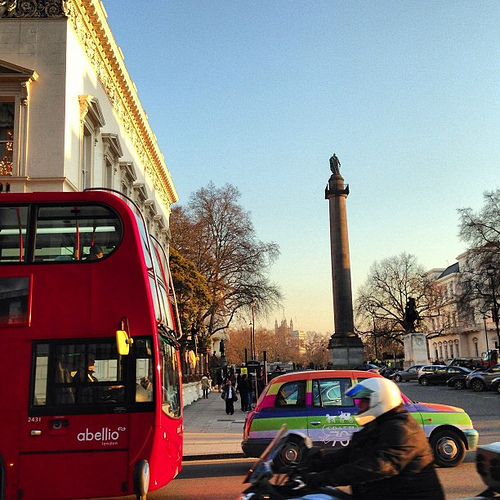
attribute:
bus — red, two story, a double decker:
[0, 187, 182, 498]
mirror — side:
[116, 328, 131, 354]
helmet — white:
[345, 376, 400, 429]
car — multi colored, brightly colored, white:
[241, 369, 476, 471]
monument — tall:
[323, 149, 365, 368]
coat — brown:
[307, 411, 449, 497]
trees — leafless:
[357, 190, 499, 363]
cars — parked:
[388, 363, 498, 396]